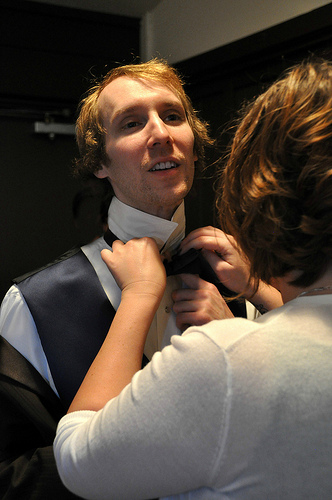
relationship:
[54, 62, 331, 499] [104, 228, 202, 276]
woman fixing tie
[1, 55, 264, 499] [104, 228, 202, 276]
man has a tie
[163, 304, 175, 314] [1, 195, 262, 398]
button on shirt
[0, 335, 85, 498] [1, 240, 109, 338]
jacket hanging off shoulder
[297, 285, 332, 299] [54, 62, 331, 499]
necklace on woman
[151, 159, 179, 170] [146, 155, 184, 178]
teeth in mouth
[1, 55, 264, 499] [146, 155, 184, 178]
man has a mouth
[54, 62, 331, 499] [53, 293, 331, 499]
woman wearing a shirt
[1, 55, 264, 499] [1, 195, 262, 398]
man wearing a shirt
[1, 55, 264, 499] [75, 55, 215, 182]
man has hair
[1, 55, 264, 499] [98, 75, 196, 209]
man has a face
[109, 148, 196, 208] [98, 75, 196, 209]
stubble on face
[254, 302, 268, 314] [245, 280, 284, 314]
tattoo on wrist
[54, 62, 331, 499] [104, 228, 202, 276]
woman tying tie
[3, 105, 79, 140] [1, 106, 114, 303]
hinge on door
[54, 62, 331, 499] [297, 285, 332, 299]
woman wearing a necklace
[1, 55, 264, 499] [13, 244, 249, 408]
man wearing a vest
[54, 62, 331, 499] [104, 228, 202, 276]
woman helping with tie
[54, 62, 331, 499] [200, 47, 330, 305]
woman has hair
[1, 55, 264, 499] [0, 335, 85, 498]
man wearing a jacket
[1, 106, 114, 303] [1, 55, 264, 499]
door behind man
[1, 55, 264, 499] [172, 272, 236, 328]
man has a left hand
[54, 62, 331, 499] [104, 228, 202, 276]
woman tying a tie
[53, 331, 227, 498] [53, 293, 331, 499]
left sleeve of shirt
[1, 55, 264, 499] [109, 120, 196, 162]
man has cheekbones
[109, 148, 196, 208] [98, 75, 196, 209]
stubble on mans face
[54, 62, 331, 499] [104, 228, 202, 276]
woman adjusting tie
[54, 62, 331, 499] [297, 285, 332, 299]
woman wearing necklace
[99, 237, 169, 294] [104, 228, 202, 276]
hand adjusting tie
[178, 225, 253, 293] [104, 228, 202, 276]
hand adjusting tie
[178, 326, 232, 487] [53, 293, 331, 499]
seam in shirt